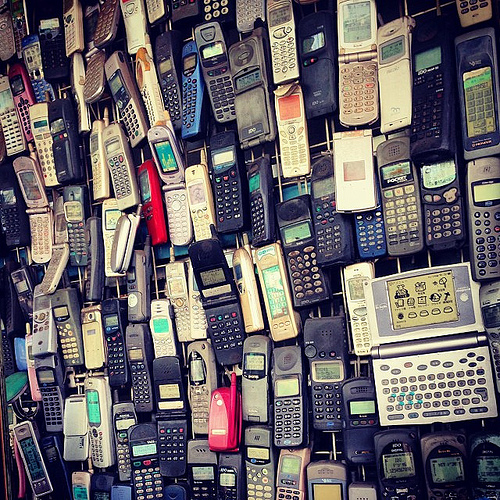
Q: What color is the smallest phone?
A: Pink.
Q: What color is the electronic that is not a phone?
A: Silver.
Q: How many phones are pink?
A: Three.